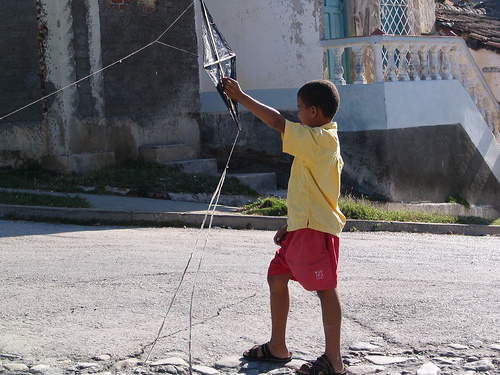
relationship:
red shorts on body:
[269, 229, 353, 292] [237, 46, 363, 359]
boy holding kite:
[218, 75, 346, 375] [162, 13, 338, 176]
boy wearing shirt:
[225, 54, 387, 374] [244, 90, 356, 240]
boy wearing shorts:
[218, 75, 346, 375] [262, 214, 356, 298]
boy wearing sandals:
[218, 75, 346, 375] [233, 337, 355, 373]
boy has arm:
[218, 75, 346, 375] [237, 90, 285, 134]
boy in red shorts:
[218, 75, 346, 375] [263, 226, 342, 292]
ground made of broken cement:
[0, 217, 499, 373] [1, 339, 499, 374]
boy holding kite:
[218, 75, 346, 375] [195, 2, 251, 136]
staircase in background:
[313, 38, 497, 203] [188, 31, 485, 131]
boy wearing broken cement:
[218, 75, 346, 375] [1, 339, 499, 374]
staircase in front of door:
[313, 38, 500, 183] [313, 0, 363, 87]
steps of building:
[150, 137, 285, 196] [195, 11, 479, 196]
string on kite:
[142, 123, 239, 373] [190, 0, 245, 135]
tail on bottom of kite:
[120, 120, 261, 372] [168, 0, 269, 140]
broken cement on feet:
[1, 339, 499, 374] [232, 341, 326, 370]